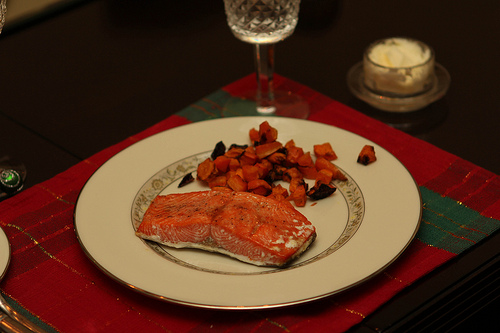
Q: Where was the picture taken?
A: Dining room.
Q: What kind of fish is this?
A: Salmon.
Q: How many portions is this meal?
A: One.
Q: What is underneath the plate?
A: Placemat.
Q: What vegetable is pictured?
A: Carrots.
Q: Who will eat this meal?
A: A man.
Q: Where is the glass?
A: Background.